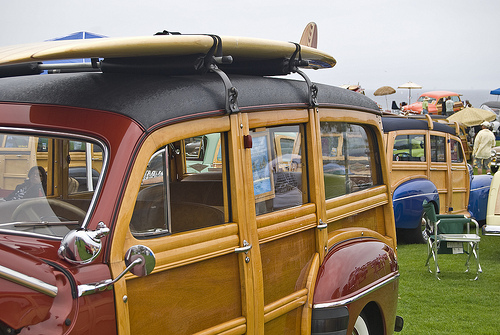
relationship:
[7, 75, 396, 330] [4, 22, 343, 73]
vehicle with surfboard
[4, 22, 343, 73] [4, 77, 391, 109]
surfboard mounted on roof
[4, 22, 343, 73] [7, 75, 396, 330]
surfboard on vehicle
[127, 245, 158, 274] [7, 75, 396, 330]
mirror of car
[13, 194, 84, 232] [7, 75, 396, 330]
wheel of car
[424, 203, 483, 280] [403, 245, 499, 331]
chair on grass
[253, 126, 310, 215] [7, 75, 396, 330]
window of car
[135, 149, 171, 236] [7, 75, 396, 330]
window of car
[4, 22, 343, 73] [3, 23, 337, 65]
surfboard colored cream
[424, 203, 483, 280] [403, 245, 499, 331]
chair sitting in grass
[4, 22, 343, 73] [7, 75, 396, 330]
surfboard on car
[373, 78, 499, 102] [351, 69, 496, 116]
umbrellas in distance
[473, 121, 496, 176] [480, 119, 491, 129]
man wearing cap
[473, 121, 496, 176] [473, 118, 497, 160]
man wearing white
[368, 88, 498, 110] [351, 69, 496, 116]
ocean in distance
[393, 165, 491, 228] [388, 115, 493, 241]
blue and brown woody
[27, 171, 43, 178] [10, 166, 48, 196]
glasses wearing woman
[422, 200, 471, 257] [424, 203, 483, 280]
green and white chair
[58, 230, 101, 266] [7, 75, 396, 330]
mirror on car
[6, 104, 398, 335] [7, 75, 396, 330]
red and brown car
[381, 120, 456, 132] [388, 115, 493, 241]
black and brown car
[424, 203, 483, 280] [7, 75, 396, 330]
chair between cars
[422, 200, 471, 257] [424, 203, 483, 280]
green lawn chair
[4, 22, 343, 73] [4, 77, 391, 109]
surfboard on roof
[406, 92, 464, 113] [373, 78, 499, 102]
car near umbrellas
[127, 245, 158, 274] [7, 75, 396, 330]
mirror on car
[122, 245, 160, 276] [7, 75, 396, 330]
silver shiny car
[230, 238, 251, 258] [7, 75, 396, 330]
handle on car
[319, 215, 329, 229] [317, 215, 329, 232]
silver door handle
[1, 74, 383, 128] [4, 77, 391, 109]
leather car roof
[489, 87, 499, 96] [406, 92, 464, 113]
umbrella near car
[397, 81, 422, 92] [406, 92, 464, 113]
umbrella near car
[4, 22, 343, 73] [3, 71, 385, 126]
surfboard on top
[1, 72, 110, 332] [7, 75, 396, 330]
front of car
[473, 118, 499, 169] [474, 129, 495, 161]
person wearing jacket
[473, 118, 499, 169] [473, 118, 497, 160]
person wearing white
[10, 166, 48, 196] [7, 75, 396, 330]
person behind car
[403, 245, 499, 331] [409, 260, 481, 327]
grass on ground